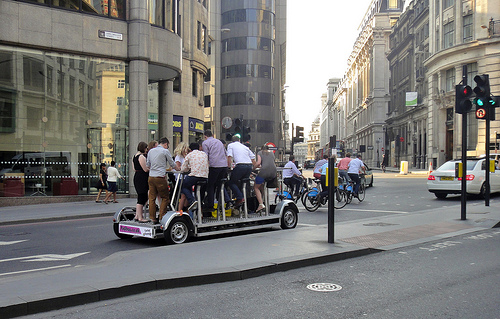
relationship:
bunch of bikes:
[341, 151, 371, 205] [290, 155, 373, 202]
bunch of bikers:
[341, 151, 371, 205] [290, 145, 368, 166]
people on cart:
[119, 120, 277, 157] [138, 211, 294, 231]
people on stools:
[119, 120, 277, 157] [239, 176, 283, 214]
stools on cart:
[239, 176, 283, 214] [138, 211, 294, 231]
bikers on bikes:
[290, 145, 368, 166] [290, 155, 373, 202]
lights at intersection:
[437, 65, 500, 143] [410, 170, 441, 226]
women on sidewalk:
[95, 145, 120, 226] [28, 187, 72, 207]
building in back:
[324, 75, 386, 141] [376, 10, 389, 27]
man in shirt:
[204, 134, 228, 170] [216, 160, 224, 164]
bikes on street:
[290, 155, 373, 202] [393, 168, 418, 218]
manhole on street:
[305, 276, 338, 302] [393, 168, 418, 218]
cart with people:
[138, 211, 294, 231] [119, 120, 277, 157]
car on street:
[429, 154, 495, 194] [393, 168, 418, 218]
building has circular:
[324, 75, 386, 141] [225, 2, 300, 46]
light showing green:
[474, 96, 485, 120] [476, 98, 487, 106]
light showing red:
[474, 96, 485, 120] [462, 84, 469, 97]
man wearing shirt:
[204, 134, 228, 170] [216, 160, 224, 164]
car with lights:
[429, 154, 495, 194] [437, 65, 500, 143]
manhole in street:
[305, 276, 338, 302] [393, 168, 418, 218]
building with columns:
[324, 75, 386, 141] [366, 29, 389, 125]